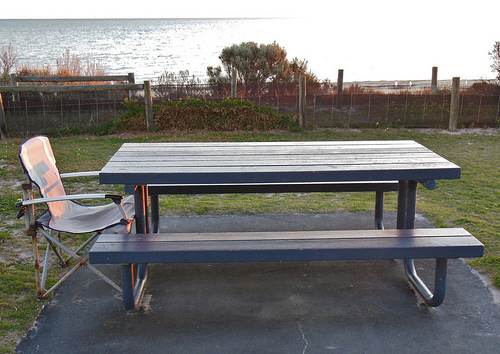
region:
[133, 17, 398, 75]
the sun is on the water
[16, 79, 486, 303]
the bench is empty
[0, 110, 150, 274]
the chair is on the left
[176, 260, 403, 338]
the ground under the bench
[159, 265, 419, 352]
the ground is grey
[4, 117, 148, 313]
the chair is orange and grey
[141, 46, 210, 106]
the tree is bare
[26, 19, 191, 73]
the water is calm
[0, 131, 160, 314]
the chair is a folding chair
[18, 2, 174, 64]
the ocean is vast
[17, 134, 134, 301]
A folding chair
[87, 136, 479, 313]
A large picnic table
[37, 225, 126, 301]
legs of a folding chair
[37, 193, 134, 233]
seat of a folding chair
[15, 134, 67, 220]
Backrest of a folding chair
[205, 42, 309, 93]
A large sage bush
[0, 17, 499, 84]
The ocean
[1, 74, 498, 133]
A stretch of fencing with posts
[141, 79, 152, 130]
a wooden fence post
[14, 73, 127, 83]
wooden crossmember on a fence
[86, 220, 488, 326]
this is a bench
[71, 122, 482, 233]
this is a table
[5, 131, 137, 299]
this is a chair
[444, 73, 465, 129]
this is a post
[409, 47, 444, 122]
this is a post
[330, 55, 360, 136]
this is a post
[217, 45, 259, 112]
this is a post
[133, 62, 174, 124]
this is a post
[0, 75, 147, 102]
this is a post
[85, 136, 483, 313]
A wooden picnic table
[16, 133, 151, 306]
A cloth chair by a table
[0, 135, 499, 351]
A small grassy field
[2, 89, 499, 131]
A short, metal fence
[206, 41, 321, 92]
a large, full bush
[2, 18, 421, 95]
A large body of water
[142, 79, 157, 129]
A wooden fence post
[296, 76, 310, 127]
A wooden fence post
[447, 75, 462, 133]
A wooden fence post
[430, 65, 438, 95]
A wooden fence post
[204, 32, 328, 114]
this is a tree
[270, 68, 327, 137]
this is a post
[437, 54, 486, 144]
this is a post